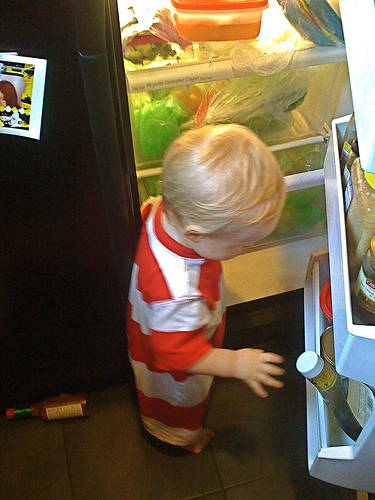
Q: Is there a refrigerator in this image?
A: Yes, there is a refrigerator.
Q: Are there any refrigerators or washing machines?
A: Yes, there is a refrigerator.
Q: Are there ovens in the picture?
A: No, there are no ovens.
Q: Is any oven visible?
A: No, there are no ovens.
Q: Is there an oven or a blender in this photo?
A: No, there are no ovens or blenders.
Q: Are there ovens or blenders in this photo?
A: No, there are no ovens or blenders.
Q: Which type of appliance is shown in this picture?
A: The appliance is a refrigerator.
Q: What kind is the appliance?
A: The appliance is a refrigerator.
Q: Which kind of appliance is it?
A: The appliance is a refrigerator.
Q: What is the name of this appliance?
A: This is a refrigerator.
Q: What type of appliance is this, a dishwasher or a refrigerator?
A: This is a refrigerator.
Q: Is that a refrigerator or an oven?
A: That is a refrigerator.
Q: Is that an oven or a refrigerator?
A: That is a refrigerator.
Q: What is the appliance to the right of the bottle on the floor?
A: The appliance is a refrigerator.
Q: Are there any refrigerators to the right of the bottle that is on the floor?
A: Yes, there is a refrigerator to the right of the bottle.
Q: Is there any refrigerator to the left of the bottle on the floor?
A: No, the refrigerator is to the right of the bottle.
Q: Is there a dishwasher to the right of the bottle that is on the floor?
A: No, there is a refrigerator to the right of the bottle.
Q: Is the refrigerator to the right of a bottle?
A: Yes, the refrigerator is to the right of a bottle.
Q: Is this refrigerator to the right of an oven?
A: No, the refrigerator is to the right of a bottle.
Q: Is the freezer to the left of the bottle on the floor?
A: No, the freezer is to the right of the bottle.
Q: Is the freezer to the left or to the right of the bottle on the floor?
A: The freezer is to the right of the bottle.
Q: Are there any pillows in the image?
A: No, there are no pillows.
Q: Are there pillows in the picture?
A: No, there are no pillows.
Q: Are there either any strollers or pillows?
A: No, there are no pillows or strollers.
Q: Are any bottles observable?
A: Yes, there is a bottle.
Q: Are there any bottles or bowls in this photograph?
A: Yes, there is a bottle.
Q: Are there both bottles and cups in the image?
A: No, there is a bottle but no cups.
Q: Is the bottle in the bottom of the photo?
A: Yes, the bottle is in the bottom of the image.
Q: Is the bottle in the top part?
A: No, the bottle is in the bottom of the image.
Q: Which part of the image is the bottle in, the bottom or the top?
A: The bottle is in the bottom of the image.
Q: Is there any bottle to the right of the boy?
A: Yes, there is a bottle to the right of the boy.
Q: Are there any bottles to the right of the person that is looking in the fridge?
A: Yes, there is a bottle to the right of the boy.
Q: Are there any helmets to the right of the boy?
A: No, there is a bottle to the right of the boy.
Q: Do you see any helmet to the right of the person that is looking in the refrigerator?
A: No, there is a bottle to the right of the boy.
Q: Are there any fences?
A: No, there are no fences.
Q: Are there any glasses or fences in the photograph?
A: No, there are no fences or glasses.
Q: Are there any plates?
A: No, there are no plates.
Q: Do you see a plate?
A: No, there are no plates.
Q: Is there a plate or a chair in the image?
A: No, there are no plates or chairs.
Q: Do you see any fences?
A: No, there are no fences.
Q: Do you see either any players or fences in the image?
A: No, there are no fences or players.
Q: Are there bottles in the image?
A: Yes, there is a bottle.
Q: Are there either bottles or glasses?
A: Yes, there is a bottle.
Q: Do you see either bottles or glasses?
A: Yes, there is a bottle.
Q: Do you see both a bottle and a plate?
A: No, there is a bottle but no plates.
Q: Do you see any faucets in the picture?
A: No, there are no faucets.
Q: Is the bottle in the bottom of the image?
A: Yes, the bottle is in the bottom of the image.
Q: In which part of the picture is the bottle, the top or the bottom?
A: The bottle is in the bottom of the image.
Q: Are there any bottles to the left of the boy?
A: Yes, there is a bottle to the left of the boy.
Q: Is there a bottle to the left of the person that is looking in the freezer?
A: Yes, there is a bottle to the left of the boy.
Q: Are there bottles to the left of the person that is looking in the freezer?
A: Yes, there is a bottle to the left of the boy.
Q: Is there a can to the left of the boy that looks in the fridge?
A: No, there is a bottle to the left of the boy.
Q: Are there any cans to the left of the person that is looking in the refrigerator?
A: No, there is a bottle to the left of the boy.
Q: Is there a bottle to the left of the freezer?
A: Yes, there is a bottle to the left of the freezer.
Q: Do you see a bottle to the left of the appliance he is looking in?
A: Yes, there is a bottle to the left of the freezer.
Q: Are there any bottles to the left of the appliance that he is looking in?
A: Yes, there is a bottle to the left of the freezer.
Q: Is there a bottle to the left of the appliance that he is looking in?
A: Yes, there is a bottle to the left of the freezer.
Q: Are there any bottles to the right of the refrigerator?
A: No, the bottle is to the left of the refrigerator.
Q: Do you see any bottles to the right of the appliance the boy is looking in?
A: No, the bottle is to the left of the refrigerator.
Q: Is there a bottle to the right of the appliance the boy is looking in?
A: No, the bottle is to the left of the refrigerator.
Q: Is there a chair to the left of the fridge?
A: No, there is a bottle to the left of the fridge.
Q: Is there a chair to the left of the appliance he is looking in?
A: No, there is a bottle to the left of the fridge.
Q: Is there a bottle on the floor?
A: Yes, there is a bottle on the floor.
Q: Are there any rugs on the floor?
A: No, there is a bottle on the floor.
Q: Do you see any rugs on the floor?
A: No, there is a bottle on the floor.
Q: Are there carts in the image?
A: No, there are no carts.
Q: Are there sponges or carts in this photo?
A: No, there are no carts or sponges.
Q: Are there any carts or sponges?
A: No, there are no carts or sponges.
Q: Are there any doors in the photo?
A: Yes, there is a door.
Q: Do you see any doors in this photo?
A: Yes, there is a door.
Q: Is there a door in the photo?
A: Yes, there is a door.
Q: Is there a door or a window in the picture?
A: Yes, there is a door.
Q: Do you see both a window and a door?
A: No, there is a door but no windows.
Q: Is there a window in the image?
A: No, there are no windows.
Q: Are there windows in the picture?
A: No, there are no windows.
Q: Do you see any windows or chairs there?
A: No, there are no windows or chairs.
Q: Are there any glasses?
A: No, there are no glasses.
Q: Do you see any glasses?
A: No, there are no glasses.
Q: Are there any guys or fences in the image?
A: No, there are no fences or guys.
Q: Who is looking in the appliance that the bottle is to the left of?
A: The boy is looking in the refrigerator.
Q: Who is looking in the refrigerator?
A: The boy is looking in the refrigerator.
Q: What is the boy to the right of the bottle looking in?
A: The boy is looking in the refrigerator.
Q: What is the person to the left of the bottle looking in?
A: The boy is looking in the refrigerator.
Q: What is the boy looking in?
A: The boy is looking in the refrigerator.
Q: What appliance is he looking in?
A: The boy is looking in the freezer.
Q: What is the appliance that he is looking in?
A: The appliance is a refrigerator.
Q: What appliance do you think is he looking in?
A: The boy is looking in the freezer.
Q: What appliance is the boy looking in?
A: The boy is looking in the freezer.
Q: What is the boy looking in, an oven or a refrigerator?
A: The boy is looking in a refrigerator.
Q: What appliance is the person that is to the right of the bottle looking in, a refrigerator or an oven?
A: The boy is looking in a refrigerator.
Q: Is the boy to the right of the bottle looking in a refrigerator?
A: Yes, the boy is looking in a refrigerator.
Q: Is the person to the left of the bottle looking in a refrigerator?
A: Yes, the boy is looking in a refrigerator.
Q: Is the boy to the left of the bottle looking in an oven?
A: No, the boy is looking in a refrigerator.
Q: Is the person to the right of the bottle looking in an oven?
A: No, the boy is looking in a refrigerator.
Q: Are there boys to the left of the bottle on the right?
A: Yes, there is a boy to the left of the bottle.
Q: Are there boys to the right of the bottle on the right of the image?
A: No, the boy is to the left of the bottle.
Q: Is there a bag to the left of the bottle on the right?
A: No, there is a boy to the left of the bottle.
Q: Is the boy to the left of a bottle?
A: Yes, the boy is to the left of a bottle.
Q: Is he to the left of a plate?
A: No, the boy is to the left of a bottle.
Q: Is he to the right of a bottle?
A: No, the boy is to the left of a bottle.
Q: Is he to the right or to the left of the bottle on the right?
A: The boy is to the left of the bottle.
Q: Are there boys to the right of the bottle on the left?
A: Yes, there is a boy to the right of the bottle.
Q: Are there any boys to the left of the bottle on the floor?
A: No, the boy is to the right of the bottle.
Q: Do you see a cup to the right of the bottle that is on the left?
A: No, there is a boy to the right of the bottle.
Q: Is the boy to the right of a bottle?
A: Yes, the boy is to the right of a bottle.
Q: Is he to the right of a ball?
A: No, the boy is to the right of a bottle.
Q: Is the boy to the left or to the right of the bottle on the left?
A: The boy is to the right of the bottle.